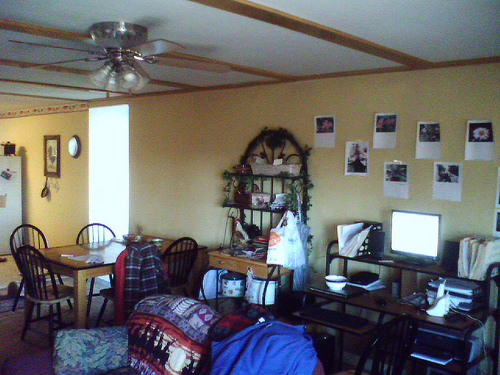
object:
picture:
[418, 122, 440, 143]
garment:
[208, 318, 320, 375]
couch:
[0, 294, 323, 375]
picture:
[385, 163, 407, 182]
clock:
[68, 135, 82, 158]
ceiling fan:
[7, 21, 232, 99]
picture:
[316, 117, 334, 133]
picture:
[375, 115, 396, 134]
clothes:
[114, 240, 173, 325]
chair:
[76, 223, 118, 317]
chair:
[94, 236, 198, 326]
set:
[7, 222, 198, 348]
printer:
[395, 233, 500, 375]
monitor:
[383, 205, 442, 267]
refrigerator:
[0, 159, 27, 261]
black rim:
[67, 134, 81, 158]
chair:
[16, 244, 75, 346]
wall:
[0, 64, 500, 286]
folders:
[441, 233, 500, 281]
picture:
[434, 161, 460, 185]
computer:
[386, 208, 443, 266]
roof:
[1, 1, 500, 114]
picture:
[468, 120, 493, 141]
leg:
[72, 271, 87, 331]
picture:
[42, 134, 62, 179]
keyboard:
[303, 307, 369, 330]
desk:
[297, 236, 500, 375]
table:
[31, 240, 211, 333]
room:
[0, 0, 500, 375]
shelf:
[398, 323, 500, 374]